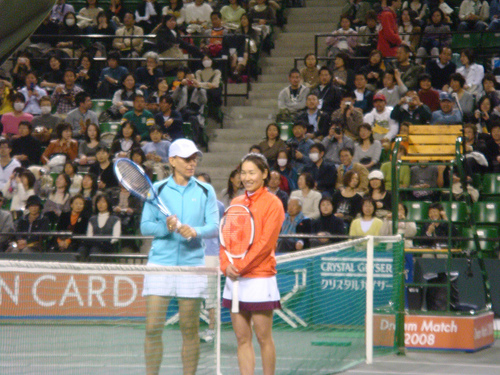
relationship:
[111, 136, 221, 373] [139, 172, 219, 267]
woman in jacket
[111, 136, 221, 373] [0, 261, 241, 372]
woman beside net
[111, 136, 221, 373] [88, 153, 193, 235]
woman with racket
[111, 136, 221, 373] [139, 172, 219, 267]
woman with jacket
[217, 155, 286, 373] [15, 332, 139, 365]
player standing on court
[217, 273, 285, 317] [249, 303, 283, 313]
skirt with trim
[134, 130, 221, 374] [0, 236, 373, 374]
player on side of net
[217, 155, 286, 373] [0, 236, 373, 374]
player on side of net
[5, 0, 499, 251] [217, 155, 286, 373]
rows behind player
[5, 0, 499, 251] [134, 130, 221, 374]
rows behind player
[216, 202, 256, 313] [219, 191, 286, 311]
racket in front of body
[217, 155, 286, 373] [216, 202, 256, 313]
player with racket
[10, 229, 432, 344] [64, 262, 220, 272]
advertisements over partition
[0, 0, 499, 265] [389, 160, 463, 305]
chair on platform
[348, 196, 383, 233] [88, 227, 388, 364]
woman seated close to net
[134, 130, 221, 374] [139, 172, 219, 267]
player in jacket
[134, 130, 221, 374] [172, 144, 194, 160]
player in cap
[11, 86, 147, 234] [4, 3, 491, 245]
audience in stands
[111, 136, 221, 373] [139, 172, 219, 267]
woman wearing jacket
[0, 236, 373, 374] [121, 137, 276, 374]
net between women